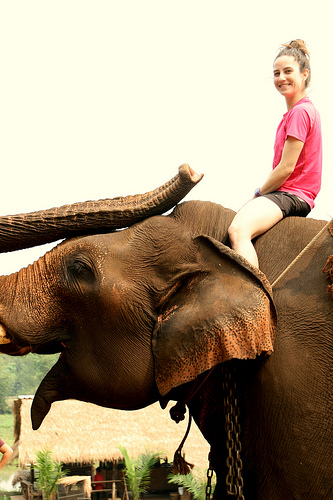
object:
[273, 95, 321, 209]
shirt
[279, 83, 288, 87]
teeth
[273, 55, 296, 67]
forehead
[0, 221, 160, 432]
face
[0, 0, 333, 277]
sky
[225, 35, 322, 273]
lady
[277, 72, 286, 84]
nose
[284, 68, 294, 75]
eyes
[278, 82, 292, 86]
lips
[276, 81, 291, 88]
mouth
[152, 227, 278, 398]
ear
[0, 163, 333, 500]
elephant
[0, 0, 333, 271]
clouds